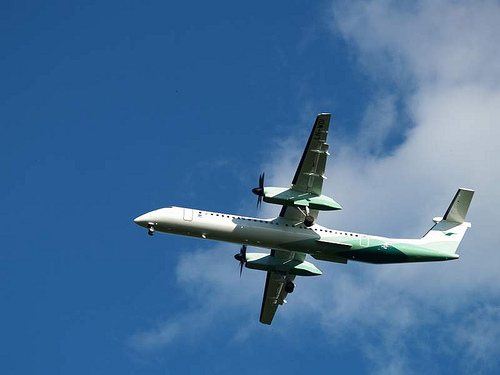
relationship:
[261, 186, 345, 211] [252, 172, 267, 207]
engine has propeller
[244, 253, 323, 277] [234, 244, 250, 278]
engine has propeller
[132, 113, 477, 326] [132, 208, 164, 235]
airplane has nose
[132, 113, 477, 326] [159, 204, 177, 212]
airplane has cockpit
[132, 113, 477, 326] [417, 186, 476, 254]
airplane has tail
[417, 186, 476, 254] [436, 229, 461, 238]
tail has logo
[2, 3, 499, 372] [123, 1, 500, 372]
sky has clouds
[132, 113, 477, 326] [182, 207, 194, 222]
airplane has door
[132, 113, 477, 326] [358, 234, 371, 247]
airplane has door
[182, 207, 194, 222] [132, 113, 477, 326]
door on front of airplane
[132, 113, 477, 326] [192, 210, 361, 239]
airplane has windows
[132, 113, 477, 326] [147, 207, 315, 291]
airplane has landing gear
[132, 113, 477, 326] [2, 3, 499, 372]
airplane in sky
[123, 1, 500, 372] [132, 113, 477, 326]
clouds above airplane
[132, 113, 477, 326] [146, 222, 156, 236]
airplane has front landing gear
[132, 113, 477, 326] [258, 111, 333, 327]
airplane has wings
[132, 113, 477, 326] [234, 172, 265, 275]
airplane has propellers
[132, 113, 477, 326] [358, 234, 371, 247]
airplane has rear door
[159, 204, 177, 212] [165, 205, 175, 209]
cockpit has window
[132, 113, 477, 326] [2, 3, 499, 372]
airplane flying in sky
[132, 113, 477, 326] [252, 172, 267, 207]
airplane has propeller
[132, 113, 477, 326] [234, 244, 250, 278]
airplane has propeller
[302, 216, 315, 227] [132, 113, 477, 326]
wheel under airplane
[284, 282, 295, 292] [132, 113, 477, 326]
wheel under airplane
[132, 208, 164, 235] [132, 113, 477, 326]
nose on front of airplane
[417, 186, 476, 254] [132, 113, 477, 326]
tail on rear of airplane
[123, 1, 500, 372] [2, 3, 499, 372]
clouds are in sky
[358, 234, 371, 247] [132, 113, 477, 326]
door on rear of airplane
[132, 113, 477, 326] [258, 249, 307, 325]
airplane has right wing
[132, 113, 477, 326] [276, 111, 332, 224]
airplane has left wing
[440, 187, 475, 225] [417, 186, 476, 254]
wing on tail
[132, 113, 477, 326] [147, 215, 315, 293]
airplane has wheels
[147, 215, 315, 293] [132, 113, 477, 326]
wheels are under airplane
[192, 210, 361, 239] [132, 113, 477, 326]
windows are on side of airplane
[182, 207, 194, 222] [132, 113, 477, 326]
door near front of airplane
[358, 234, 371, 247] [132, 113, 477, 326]
door near rear of airplane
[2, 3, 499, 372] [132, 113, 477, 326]
sky above airplane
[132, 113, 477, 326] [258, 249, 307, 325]
airplane has wing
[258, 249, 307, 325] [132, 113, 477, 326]
wing on right side of airplane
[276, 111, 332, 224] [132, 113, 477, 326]
wing on left side of airplane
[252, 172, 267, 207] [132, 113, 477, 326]
propeller on airplane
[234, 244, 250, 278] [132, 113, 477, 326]
propeller on airplane